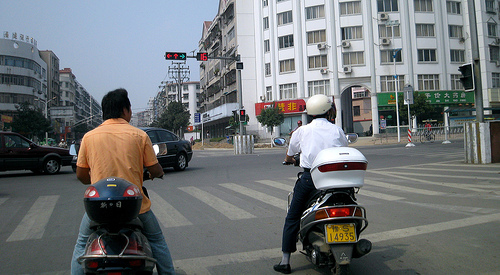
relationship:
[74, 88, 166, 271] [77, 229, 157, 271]
man riding moped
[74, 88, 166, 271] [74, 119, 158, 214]
man wearing shirt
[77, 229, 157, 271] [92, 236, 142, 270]
moped has back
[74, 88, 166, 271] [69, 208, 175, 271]
man wearing jeans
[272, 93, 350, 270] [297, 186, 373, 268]
person riding moped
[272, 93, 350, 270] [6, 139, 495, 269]
person on top of road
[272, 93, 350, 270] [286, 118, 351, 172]
person wearing shirt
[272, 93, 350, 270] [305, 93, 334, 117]
person wearing helmet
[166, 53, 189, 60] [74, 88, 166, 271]
light cautioning man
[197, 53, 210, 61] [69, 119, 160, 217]
light cautioning man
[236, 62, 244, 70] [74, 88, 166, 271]
light cautioning man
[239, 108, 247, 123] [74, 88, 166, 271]
light cautioning man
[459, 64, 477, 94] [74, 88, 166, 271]
light cautioning man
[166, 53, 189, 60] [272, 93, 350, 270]
light cautioning person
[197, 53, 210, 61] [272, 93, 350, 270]
light cautioning person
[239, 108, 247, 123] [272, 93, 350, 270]
light cautioning person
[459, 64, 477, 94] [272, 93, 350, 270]
light cautioning person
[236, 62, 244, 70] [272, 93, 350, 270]
light cautioning person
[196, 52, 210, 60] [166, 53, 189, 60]
number beside light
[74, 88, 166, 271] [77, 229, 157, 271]
man on moped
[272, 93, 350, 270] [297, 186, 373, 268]
person on moped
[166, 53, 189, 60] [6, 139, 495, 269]
light over road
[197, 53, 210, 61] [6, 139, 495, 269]
light over road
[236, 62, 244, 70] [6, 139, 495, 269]
light over road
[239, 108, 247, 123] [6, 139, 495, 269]
light over road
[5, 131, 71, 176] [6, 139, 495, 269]
car on top of road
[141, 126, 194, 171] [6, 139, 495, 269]
car on top of road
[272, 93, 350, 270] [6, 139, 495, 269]
person crossing road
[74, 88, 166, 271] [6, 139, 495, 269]
man crossing road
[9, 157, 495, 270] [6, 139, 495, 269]
lines are on top of road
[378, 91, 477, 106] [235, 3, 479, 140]
sign on side of building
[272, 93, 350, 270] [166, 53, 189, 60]
person stopped at light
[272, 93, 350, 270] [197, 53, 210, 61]
person stopped at light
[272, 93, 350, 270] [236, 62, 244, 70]
person stopped at light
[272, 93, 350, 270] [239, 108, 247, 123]
person stopped at light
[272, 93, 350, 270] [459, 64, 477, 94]
person stopped at light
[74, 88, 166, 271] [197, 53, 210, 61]
man stopped at light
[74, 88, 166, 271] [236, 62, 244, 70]
man stopped at light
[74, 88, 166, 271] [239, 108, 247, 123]
man stopped at light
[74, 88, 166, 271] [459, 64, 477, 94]
man stopped at light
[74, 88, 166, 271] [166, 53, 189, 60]
man stopped at light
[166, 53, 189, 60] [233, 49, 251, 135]
light on top of pole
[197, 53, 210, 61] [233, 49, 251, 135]
light on top of pole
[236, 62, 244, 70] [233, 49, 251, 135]
light on top of pole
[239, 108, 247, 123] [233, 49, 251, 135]
light on top of pole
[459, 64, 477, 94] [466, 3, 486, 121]
light on top of pole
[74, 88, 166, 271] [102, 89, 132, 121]
man has hair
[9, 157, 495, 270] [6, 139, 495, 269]
lines on top of road